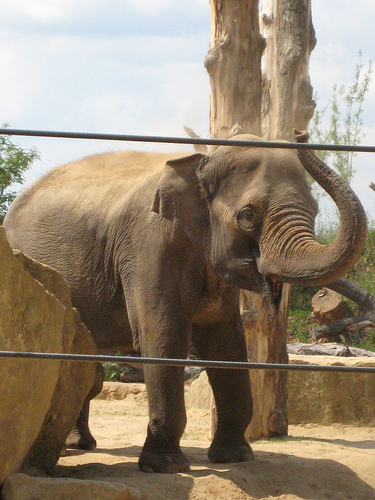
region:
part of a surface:
[265, 458, 280, 481]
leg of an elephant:
[166, 407, 170, 448]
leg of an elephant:
[175, 275, 179, 285]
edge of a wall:
[341, 362, 346, 371]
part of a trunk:
[279, 271, 287, 298]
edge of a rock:
[18, 350, 50, 401]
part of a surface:
[315, 425, 328, 473]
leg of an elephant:
[170, 398, 171, 422]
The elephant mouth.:
[255, 267, 290, 315]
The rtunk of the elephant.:
[268, 123, 373, 285]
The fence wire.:
[2, 348, 373, 378]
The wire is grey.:
[0, 342, 373, 377]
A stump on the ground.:
[307, 284, 353, 322]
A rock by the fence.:
[0, 225, 100, 497]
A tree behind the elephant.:
[241, 322, 290, 430]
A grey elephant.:
[8, 130, 365, 466]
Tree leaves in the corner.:
[0, 117, 46, 217]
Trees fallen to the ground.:
[284, 302, 373, 359]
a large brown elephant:
[0, 126, 367, 472]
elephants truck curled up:
[273, 128, 366, 286]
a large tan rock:
[0, 223, 97, 474]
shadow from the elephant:
[88, 439, 371, 496]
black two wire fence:
[0, 125, 371, 372]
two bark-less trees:
[201, 0, 313, 139]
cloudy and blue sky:
[0, 0, 210, 136]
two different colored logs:
[308, 279, 371, 339]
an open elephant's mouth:
[250, 273, 285, 318]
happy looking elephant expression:
[149, 127, 368, 315]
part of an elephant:
[157, 328, 173, 397]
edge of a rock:
[299, 373, 310, 410]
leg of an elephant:
[227, 400, 236, 409]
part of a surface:
[74, 425, 92, 450]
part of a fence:
[301, 397, 312, 413]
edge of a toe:
[217, 443, 230, 454]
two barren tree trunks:
[204, 0, 324, 136]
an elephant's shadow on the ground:
[212, 460, 372, 496]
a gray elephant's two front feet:
[140, 420, 254, 468]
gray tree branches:
[319, 269, 373, 337]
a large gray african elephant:
[27, 129, 365, 431]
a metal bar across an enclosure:
[20, 334, 367, 377]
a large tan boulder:
[0, 226, 111, 486]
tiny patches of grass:
[103, 404, 138, 429]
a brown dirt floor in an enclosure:
[104, 429, 131, 462]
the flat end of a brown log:
[311, 287, 339, 312]